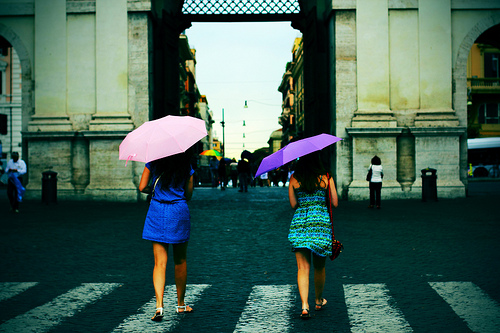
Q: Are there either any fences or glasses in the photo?
A: No, there are no fences or glasses.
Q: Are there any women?
A: Yes, there is a woman.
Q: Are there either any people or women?
A: Yes, there is a woman.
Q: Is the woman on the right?
A: Yes, the woman is on the right of the image.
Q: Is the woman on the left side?
A: No, the woman is on the right of the image.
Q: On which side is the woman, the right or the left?
A: The woman is on the right of the image.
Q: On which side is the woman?
A: The woman is on the right of the image.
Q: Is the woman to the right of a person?
A: Yes, the woman is to the right of a person.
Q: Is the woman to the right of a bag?
A: No, the woman is to the right of a person.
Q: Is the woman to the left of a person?
A: No, the woman is to the right of a person.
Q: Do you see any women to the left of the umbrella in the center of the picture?
A: No, the woman is to the right of the umbrella.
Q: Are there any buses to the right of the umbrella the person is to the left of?
A: No, there is a woman to the right of the umbrella.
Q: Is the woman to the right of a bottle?
A: No, the woman is to the right of the umbrella.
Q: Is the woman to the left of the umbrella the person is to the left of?
A: No, the woman is to the right of the umbrella.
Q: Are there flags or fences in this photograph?
A: No, there are no fences or flags.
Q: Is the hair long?
A: Yes, the hair is long.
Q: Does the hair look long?
A: Yes, the hair is long.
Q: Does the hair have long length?
A: Yes, the hair is long.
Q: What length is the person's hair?
A: The hair is long.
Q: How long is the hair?
A: The hair is long.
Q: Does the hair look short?
A: No, the hair is long.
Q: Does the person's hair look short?
A: No, the hair is long.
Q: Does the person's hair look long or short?
A: The hair is long.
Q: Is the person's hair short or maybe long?
A: The hair is long.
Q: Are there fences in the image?
A: No, there are no fences.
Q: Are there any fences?
A: No, there are no fences.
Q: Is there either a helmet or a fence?
A: No, there are no fences or helmets.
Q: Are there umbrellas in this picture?
A: Yes, there is an umbrella.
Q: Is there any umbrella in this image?
A: Yes, there is an umbrella.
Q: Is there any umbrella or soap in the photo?
A: Yes, there is an umbrella.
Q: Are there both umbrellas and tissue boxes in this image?
A: No, there is an umbrella but no tissue boxes.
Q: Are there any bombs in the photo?
A: No, there are no bombs.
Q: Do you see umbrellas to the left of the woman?
A: Yes, there is an umbrella to the left of the woman.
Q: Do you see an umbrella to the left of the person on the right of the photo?
A: Yes, there is an umbrella to the left of the woman.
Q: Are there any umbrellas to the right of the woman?
A: No, the umbrella is to the left of the woman.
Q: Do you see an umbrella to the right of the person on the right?
A: No, the umbrella is to the left of the woman.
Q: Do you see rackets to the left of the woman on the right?
A: No, there is an umbrella to the left of the woman.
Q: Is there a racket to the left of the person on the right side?
A: No, there is an umbrella to the left of the woman.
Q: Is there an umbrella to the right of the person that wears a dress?
A: Yes, there is an umbrella to the right of the person.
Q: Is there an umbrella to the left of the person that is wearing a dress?
A: No, the umbrella is to the right of the person.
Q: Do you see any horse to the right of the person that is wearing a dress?
A: No, there is an umbrella to the right of the person.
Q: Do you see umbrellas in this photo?
A: Yes, there is an umbrella.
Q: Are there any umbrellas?
A: Yes, there is an umbrella.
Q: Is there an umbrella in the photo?
A: Yes, there is an umbrella.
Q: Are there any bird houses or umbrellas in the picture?
A: Yes, there is an umbrella.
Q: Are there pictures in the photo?
A: No, there are no pictures.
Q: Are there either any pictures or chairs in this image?
A: No, there are no pictures or chairs.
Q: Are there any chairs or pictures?
A: No, there are no pictures or chairs.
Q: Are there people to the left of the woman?
A: Yes, there is a person to the left of the woman.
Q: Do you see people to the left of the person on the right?
A: Yes, there is a person to the left of the woman.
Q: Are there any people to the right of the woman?
A: No, the person is to the left of the woman.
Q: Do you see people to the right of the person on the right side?
A: No, the person is to the left of the woman.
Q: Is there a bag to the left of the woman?
A: No, there is a person to the left of the woman.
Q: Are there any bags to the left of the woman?
A: No, there is a person to the left of the woman.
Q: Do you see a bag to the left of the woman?
A: No, there is a person to the left of the woman.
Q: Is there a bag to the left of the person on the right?
A: No, there is a person to the left of the woman.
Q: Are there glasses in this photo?
A: No, there are no glasses.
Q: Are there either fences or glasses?
A: No, there are no glasses or fences.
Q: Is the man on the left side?
A: Yes, the man is on the left of the image.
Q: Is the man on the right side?
A: No, the man is on the left of the image.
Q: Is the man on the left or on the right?
A: The man is on the left of the image.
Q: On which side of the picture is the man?
A: The man is on the left of the image.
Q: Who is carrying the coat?
A: The man is carrying the coat.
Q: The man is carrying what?
A: The man is carrying a coat.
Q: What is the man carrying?
A: The man is carrying a coat.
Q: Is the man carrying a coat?
A: Yes, the man is carrying a coat.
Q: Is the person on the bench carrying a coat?
A: Yes, the man is carrying a coat.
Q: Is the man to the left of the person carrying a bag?
A: No, the man is carrying a coat.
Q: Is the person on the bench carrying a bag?
A: No, the man is carrying a coat.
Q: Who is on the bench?
A: The man is on the bench.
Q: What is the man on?
A: The man is on the bench.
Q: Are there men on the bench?
A: Yes, there is a man on the bench.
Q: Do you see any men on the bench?
A: Yes, there is a man on the bench.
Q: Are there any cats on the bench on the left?
A: No, there is a man on the bench.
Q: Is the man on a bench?
A: Yes, the man is on a bench.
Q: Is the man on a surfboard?
A: No, the man is on a bench.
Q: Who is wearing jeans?
A: The man is wearing jeans.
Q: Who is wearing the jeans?
A: The man is wearing jeans.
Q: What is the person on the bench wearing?
A: The man is wearing jeans.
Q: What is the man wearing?
A: The man is wearing jeans.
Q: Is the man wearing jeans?
A: Yes, the man is wearing jeans.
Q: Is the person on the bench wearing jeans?
A: Yes, the man is wearing jeans.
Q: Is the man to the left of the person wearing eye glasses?
A: No, the man is wearing jeans.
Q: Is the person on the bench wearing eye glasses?
A: No, the man is wearing jeans.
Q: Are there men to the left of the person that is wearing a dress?
A: Yes, there is a man to the left of the person.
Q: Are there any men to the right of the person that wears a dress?
A: No, the man is to the left of the person.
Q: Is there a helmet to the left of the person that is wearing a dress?
A: No, there is a man to the left of the person.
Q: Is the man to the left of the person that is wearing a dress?
A: Yes, the man is to the left of the person.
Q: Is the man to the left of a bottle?
A: No, the man is to the left of the person.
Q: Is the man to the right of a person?
A: No, the man is to the left of a person.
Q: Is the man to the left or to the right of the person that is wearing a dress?
A: The man is to the left of the person.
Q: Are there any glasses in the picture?
A: No, there are no glasses.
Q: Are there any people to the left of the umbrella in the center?
A: Yes, there is a person to the left of the umbrella.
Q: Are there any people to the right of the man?
A: Yes, there is a person to the right of the man.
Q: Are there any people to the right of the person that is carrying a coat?
A: Yes, there is a person to the right of the man.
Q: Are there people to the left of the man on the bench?
A: No, the person is to the right of the man.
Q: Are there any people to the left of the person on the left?
A: No, the person is to the right of the man.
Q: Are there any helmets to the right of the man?
A: No, there is a person to the right of the man.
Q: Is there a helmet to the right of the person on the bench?
A: No, there is a person to the right of the man.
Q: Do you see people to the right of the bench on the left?
A: Yes, there is a person to the right of the bench.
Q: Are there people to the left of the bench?
A: No, the person is to the right of the bench.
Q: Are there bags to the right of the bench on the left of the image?
A: No, there is a person to the right of the bench.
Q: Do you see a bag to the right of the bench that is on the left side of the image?
A: No, there is a person to the right of the bench.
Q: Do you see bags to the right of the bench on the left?
A: No, there is a person to the right of the bench.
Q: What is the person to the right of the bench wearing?
A: The person is wearing a dress.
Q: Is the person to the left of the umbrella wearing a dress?
A: Yes, the person is wearing a dress.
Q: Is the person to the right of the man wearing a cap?
A: No, the person is wearing a dress.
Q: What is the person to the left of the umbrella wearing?
A: The person is wearing a dress.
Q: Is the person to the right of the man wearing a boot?
A: No, the person is wearing a dress.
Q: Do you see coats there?
A: Yes, there is a coat.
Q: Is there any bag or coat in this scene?
A: Yes, there is a coat.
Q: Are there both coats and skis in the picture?
A: No, there is a coat but no skis.